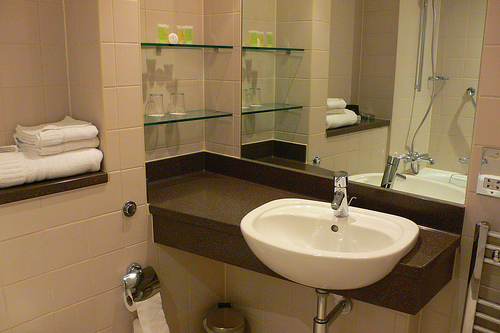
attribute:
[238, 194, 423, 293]
sink — white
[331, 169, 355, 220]
faucet — silver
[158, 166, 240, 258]
counter — brown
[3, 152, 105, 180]
towel — white, folded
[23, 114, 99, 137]
towel — folded, white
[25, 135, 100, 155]
towel — folded, white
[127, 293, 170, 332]
toilet paper — white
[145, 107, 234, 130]
shelf — glass, clear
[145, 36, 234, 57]
shelf — glass, clear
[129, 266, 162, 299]
roll — silver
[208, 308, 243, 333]
garbage can — metal, small, silver, black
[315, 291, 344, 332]
pipes — silver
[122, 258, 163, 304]
toilet paper holder — silver, metal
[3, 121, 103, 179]
towels — stacked, folded